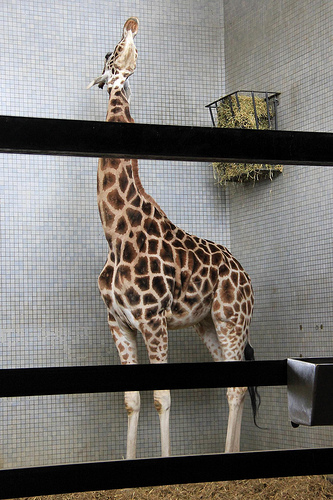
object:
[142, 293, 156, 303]
spot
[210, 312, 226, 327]
spot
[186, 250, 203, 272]
spot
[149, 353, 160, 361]
spot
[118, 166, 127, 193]
spot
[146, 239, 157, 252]
spot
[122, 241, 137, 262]
spot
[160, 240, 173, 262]
spot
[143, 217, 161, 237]
spot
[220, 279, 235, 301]
spot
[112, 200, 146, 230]
spot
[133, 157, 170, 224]
mane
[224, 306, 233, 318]
spot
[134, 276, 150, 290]
spot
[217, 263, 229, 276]
spot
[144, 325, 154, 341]
spot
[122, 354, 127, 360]
brown spot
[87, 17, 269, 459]
giraffe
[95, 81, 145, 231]
neck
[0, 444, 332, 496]
hay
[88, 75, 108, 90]
ear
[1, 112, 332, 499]
enclosure